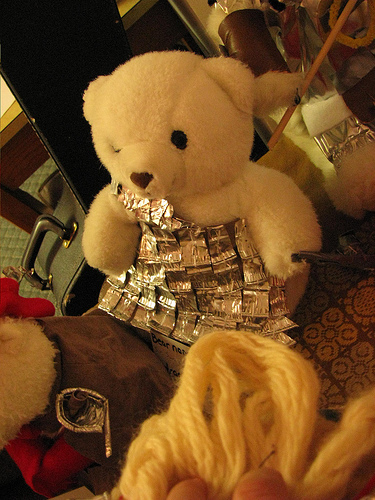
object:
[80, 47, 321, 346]
bear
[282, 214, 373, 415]
floor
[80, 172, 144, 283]
right arm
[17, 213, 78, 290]
handle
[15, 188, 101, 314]
bag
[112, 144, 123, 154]
eye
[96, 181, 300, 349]
foil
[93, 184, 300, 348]
dress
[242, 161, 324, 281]
arm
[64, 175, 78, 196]
edge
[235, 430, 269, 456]
cream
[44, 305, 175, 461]
cloth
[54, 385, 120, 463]
packet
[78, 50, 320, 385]
teddy bear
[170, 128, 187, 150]
dark eye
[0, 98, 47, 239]
table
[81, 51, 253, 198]
head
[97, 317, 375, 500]
ribbon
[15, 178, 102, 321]
box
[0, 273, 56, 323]
doll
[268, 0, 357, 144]
stick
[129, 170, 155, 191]
snout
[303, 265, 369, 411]
cloth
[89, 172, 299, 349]
clothing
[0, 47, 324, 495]
two dolls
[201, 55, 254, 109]
ear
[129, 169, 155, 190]
nose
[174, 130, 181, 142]
black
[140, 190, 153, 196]
smile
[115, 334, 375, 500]
wool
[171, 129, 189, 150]
eye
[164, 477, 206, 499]
finger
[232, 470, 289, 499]
finger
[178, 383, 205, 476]
string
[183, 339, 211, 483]
string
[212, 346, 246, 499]
string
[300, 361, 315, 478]
string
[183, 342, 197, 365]
part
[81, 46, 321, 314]
doll